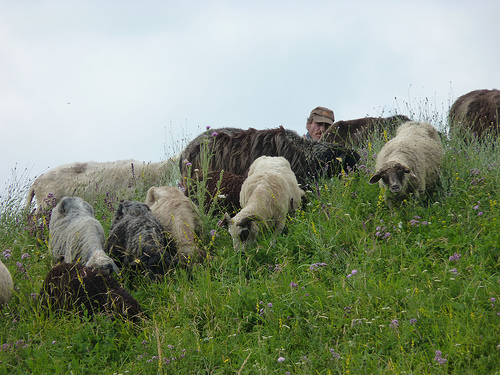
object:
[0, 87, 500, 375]
pasture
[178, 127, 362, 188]
animal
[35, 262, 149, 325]
animal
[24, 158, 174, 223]
animal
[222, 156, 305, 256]
animals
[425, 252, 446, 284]
weed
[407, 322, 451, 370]
weed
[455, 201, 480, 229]
weed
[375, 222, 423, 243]
weed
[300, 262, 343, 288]
weed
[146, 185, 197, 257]
sheep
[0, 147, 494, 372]
grass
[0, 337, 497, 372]
farmland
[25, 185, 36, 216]
tail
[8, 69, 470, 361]
field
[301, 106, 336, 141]
man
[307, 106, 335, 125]
cap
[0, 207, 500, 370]
flowers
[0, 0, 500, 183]
sky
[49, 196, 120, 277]
goat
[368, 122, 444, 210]
goat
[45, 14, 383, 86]
clouds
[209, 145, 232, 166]
hair